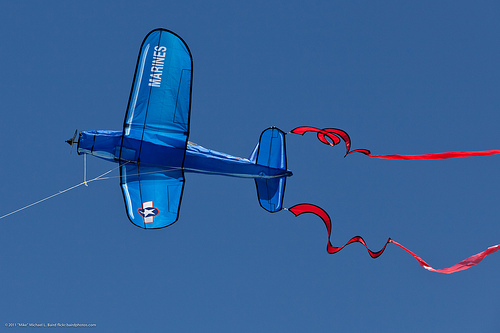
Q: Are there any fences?
A: No, there are no fences.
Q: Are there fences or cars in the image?
A: No, there are no fences or cars.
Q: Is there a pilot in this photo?
A: No, there are no pilots.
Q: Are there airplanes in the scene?
A: Yes, there is an airplane.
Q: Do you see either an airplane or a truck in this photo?
A: Yes, there is an airplane.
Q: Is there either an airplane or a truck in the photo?
A: Yes, there is an airplane.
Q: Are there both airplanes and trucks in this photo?
A: No, there is an airplane but no trucks.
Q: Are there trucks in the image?
A: No, there are no trucks.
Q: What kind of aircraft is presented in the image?
A: The aircraft is an airplane.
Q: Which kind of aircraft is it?
A: The aircraft is an airplane.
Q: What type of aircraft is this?
A: This is an airplane.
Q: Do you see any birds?
A: No, there are no birds.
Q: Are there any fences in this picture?
A: No, there are no fences.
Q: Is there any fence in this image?
A: No, there are no fences.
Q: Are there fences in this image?
A: No, there are no fences.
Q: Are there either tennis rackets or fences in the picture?
A: No, there are no fences or tennis rackets.